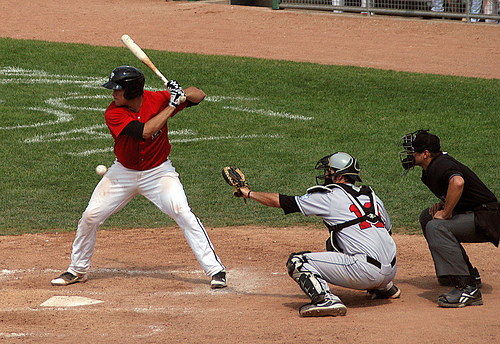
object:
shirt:
[105, 90, 188, 171]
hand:
[233, 186, 251, 198]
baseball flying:
[76, 159, 128, 195]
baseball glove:
[222, 164, 251, 197]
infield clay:
[391, 310, 499, 344]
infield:
[1, 1, 500, 344]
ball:
[95, 164, 108, 176]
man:
[398, 130, 500, 308]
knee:
[164, 207, 194, 220]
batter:
[50, 65, 228, 289]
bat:
[118, 30, 187, 85]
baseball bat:
[120, 33, 169, 83]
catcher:
[221, 151, 401, 318]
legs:
[67, 173, 134, 274]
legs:
[425, 211, 491, 288]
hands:
[433, 209, 452, 219]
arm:
[249, 189, 333, 218]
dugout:
[369, 0, 500, 23]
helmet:
[102, 65, 145, 100]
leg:
[286, 251, 375, 300]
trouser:
[66, 157, 227, 277]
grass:
[215, 61, 270, 89]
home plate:
[39, 295, 105, 306]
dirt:
[0, 310, 85, 344]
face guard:
[315, 151, 363, 185]